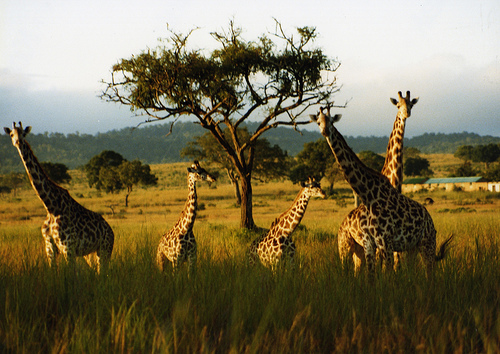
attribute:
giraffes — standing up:
[306, 80, 451, 280]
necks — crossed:
[323, 139, 409, 178]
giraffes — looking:
[154, 157, 329, 273]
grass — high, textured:
[3, 263, 484, 352]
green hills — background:
[0, 115, 184, 158]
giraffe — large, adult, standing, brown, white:
[340, 90, 418, 278]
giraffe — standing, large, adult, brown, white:
[309, 107, 454, 280]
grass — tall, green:
[2, 201, 500, 352]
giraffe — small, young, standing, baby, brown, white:
[246, 177, 326, 272]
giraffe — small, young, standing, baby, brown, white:
[156, 159, 216, 280]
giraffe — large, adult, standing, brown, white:
[3, 120, 115, 276]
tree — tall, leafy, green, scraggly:
[96, 15, 352, 229]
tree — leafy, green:
[182, 127, 296, 206]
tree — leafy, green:
[84, 150, 158, 194]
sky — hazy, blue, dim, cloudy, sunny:
[2, 1, 498, 139]